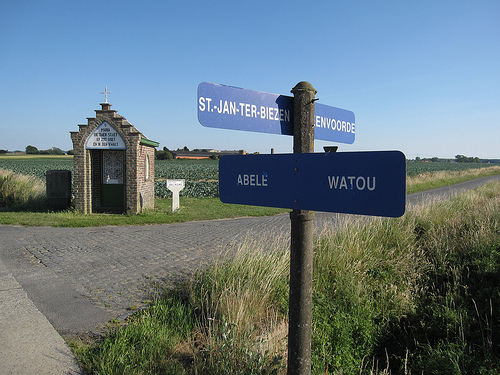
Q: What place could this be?
A: It is a field.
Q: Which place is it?
A: It is a field.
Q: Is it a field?
A: Yes, it is a field.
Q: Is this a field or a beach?
A: It is a field.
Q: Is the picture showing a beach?
A: No, the picture is showing a field.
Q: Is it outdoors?
A: Yes, it is outdoors.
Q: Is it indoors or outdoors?
A: It is outdoors.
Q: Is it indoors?
A: No, it is outdoors.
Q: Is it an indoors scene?
A: No, it is outdoors.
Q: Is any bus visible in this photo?
A: No, there are no buses.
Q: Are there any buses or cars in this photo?
A: No, there are no buses or cars.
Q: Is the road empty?
A: Yes, the road is empty.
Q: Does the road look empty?
A: Yes, the road is empty.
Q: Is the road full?
A: No, the road is empty.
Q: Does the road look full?
A: No, the road is empty.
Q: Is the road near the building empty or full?
A: The road is empty.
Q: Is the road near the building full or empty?
A: The road is empty.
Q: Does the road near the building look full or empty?
A: The road is empty.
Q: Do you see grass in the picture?
A: Yes, there is grass.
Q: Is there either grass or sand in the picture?
A: Yes, there is grass.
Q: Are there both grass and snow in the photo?
A: No, there is grass but no snow.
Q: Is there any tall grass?
A: Yes, there is tall grass.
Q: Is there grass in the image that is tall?
A: Yes, there is grass that is tall.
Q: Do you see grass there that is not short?
A: Yes, there is tall grass.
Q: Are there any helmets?
A: No, there are no helmets.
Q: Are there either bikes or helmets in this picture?
A: No, there are no helmets or bikes.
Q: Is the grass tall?
A: Yes, the grass is tall.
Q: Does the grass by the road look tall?
A: Yes, the grass is tall.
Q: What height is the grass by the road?
A: The grass is tall.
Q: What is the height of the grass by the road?
A: The grass is tall.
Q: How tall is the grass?
A: The grass is tall.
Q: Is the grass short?
A: No, the grass is tall.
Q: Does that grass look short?
A: No, the grass is tall.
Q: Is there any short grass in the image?
A: No, there is grass but it is tall.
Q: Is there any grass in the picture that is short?
A: No, there is grass but it is tall.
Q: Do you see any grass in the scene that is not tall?
A: No, there is grass but it is tall.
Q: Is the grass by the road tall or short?
A: The grass is tall.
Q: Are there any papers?
A: No, there are no papers.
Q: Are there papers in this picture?
A: No, there are no papers.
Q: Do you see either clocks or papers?
A: No, there are no papers or clocks.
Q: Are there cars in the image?
A: No, there are no cars.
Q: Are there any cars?
A: No, there are no cars.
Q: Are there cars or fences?
A: No, there are no cars or fences.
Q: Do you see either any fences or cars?
A: No, there are no cars or fences.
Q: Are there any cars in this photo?
A: No, there are no cars.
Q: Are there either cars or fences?
A: No, there are no cars or fences.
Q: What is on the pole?
A: The sign is on the pole.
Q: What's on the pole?
A: The sign is on the pole.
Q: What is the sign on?
A: The sign is on the pole.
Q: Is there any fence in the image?
A: No, there are no fences.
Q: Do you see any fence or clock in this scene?
A: No, there are no fences or clocks.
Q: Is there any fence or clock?
A: No, there are no fences or clocks.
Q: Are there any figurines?
A: No, there are no figurines.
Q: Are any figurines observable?
A: No, there are no figurines.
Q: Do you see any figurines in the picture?
A: No, there are no figurines.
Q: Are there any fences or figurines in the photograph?
A: No, there are no figurines or fences.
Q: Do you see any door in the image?
A: Yes, there is a door.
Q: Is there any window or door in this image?
A: Yes, there is a door.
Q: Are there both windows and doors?
A: No, there is a door but no windows.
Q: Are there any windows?
A: No, there are no windows.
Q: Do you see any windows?
A: No, there are no windows.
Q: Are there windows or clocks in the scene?
A: No, there are no windows or clocks.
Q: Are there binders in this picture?
A: No, there are no binders.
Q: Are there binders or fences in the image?
A: No, there are no binders or fences.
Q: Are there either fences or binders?
A: No, there are no binders or fences.